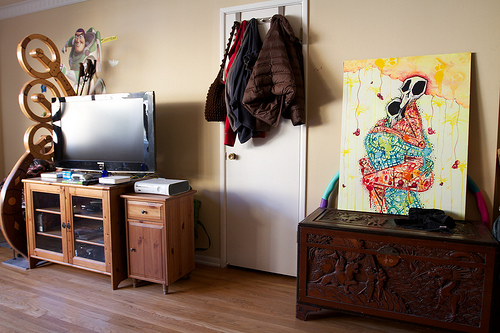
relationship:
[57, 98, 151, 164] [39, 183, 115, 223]
tv on table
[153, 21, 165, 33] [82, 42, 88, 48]
wall has sticker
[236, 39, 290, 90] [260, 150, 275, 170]
coats on door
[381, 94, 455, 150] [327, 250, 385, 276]
art on stand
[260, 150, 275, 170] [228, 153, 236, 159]
door has knob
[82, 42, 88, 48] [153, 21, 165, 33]
sticker on wall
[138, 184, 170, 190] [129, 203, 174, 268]
xbox on cabinet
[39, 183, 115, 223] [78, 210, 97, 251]
table has games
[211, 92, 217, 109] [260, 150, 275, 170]
purse on door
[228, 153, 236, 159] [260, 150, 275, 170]
knob on door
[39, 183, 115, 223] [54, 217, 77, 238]
table has doors